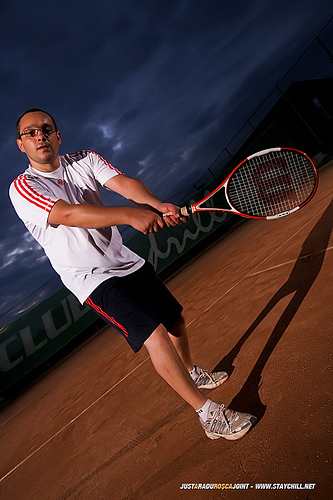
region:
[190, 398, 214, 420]
men's white ankle sock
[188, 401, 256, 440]
men's gray tennis shoes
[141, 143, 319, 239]
a red and white tennis racket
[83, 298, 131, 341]
a red design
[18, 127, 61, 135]
clear eyeglasses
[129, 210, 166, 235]
the hand of a man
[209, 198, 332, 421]
the man's shadow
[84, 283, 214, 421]
the leg of a man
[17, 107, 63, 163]
the head of a man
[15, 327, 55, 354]
a capital white letter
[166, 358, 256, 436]
two white tennis shoes on tennis player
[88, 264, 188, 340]
tennis player wearing black short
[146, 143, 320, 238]
red tennis racket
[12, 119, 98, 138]
tennis player wearing glasses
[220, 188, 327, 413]
shadow of tennis player on court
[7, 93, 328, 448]
tennis player with a red racket on court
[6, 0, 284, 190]
stormy blue skies overhead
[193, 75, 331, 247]
a stadium in background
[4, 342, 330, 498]
a clay tennis court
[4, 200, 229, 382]
a name on side of stadium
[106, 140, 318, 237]
racket is red and white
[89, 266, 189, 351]
shorts are black and red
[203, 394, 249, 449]
shoes are grey and black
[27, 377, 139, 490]
court is clay-based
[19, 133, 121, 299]
shirt is white and red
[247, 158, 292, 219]
logo on racket face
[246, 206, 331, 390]
shadow emanating from player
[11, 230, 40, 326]
day is stormy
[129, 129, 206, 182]
day is cloudy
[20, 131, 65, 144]
man wears eyeglasses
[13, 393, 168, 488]
dirt tennis court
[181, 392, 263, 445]
silver Adidas brand tennis shoes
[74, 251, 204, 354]
navy blue shorts with red stripes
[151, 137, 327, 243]
red and white tennis racket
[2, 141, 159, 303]
white jersey with red stripes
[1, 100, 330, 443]
young male tennis player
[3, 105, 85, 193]
young male wearing glasses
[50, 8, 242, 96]
overcast evening sky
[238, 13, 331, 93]
fence arouund tennis court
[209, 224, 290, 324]
chalk stripe on tennis court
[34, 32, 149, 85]
gray skies on the poster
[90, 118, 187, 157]
white clouds dotted across the sky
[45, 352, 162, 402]
long white line going across the court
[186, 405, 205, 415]
small black lines on short white socks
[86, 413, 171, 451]
skid marks on the court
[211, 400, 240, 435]
long white shoe laces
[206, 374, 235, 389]
dirt smudge at edge of sneakers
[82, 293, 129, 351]
red streak down the side of black shorts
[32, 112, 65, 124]
sweat on man's face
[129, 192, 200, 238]
man's hand holding racket